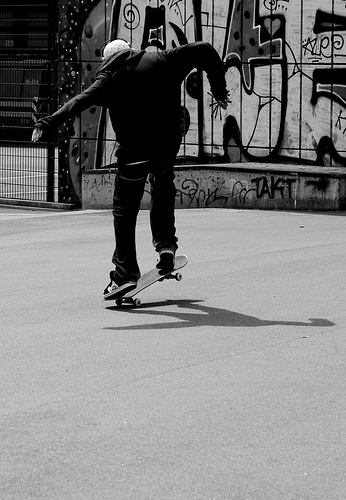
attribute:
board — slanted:
[103, 249, 202, 306]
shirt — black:
[66, 40, 226, 159]